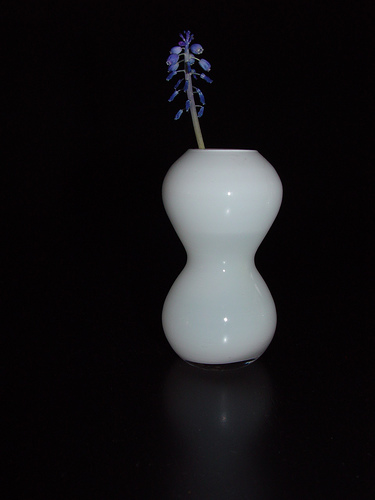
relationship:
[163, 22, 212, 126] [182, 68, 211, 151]
flowers has stem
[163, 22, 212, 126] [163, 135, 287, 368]
flowers in vase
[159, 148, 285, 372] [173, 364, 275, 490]
vase casting reflection